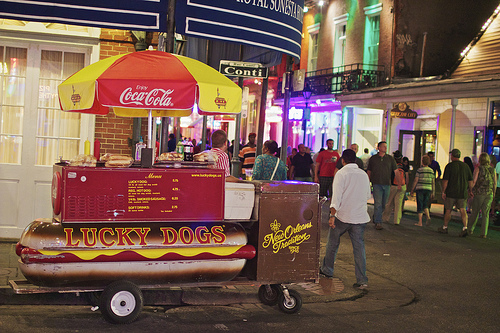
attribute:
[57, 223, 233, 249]
writing — red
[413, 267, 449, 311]
road — black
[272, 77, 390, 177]
light — purple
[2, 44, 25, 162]
window — glass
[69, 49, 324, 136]
umbrella — red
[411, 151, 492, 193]
shirt — black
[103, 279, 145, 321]
wheel — black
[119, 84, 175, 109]
writing — white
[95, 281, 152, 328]
wheel — black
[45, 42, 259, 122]
umbrella — red, yellow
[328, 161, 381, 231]
shirt — white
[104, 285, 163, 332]
wheel — white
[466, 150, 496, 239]
people — walking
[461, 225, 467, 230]
sock — white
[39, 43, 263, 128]
umbrella — coca cola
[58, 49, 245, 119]
umbrella — red, yellow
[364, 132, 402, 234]
man — walking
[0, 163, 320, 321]
cart — large, hot dog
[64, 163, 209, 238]
menu — on side